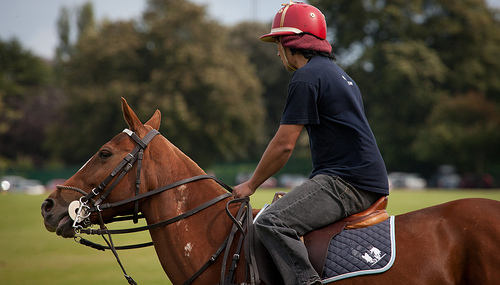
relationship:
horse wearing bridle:
[46, 106, 497, 283] [63, 191, 155, 238]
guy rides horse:
[211, 0, 391, 280] [46, 106, 497, 283]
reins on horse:
[92, 142, 205, 262] [67, 126, 486, 282]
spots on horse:
[181, 236, 198, 262] [49, 125, 253, 247]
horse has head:
[46, 106, 497, 283] [38, 95, 173, 237]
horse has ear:
[40, 96, 500, 285] [119, 95, 144, 130]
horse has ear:
[40, 96, 500, 285] [145, 105, 163, 131]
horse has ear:
[40, 96, 500, 285] [137, 102, 169, 133]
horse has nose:
[46, 106, 497, 283] [33, 197, 62, 228]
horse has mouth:
[46, 106, 497, 283] [35, 192, 83, 239]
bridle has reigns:
[52, 127, 157, 238] [75, 174, 237, 250]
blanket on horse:
[323, 213, 398, 280] [46, 106, 497, 283]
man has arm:
[230, 2, 390, 284] [233, 85, 318, 202]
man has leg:
[230, 2, 390, 284] [253, 172, 377, 283]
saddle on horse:
[348, 194, 405, 230] [40, 96, 500, 285]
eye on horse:
[98, 146, 114, 161] [16, 72, 498, 281]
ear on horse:
[117, 95, 140, 127] [40, 96, 500, 285]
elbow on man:
[263, 125, 301, 167] [212, 2, 408, 283]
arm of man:
[241, 110, 306, 189] [248, 35, 357, 268]